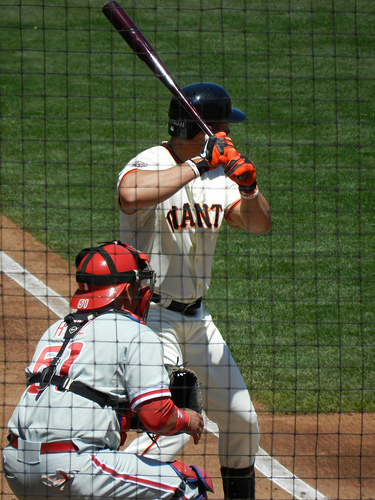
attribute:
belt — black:
[155, 290, 207, 313]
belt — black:
[154, 291, 218, 321]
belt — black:
[153, 295, 207, 318]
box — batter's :
[28, 364, 312, 498]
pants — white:
[124, 296, 260, 484]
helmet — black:
[160, 78, 247, 135]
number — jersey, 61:
[19, 340, 82, 393]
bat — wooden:
[107, 37, 229, 180]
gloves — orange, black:
[185, 143, 255, 189]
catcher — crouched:
[18, 214, 165, 494]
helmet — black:
[129, 59, 287, 132]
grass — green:
[282, 268, 372, 351]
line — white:
[54, 290, 341, 476]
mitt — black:
[177, 351, 202, 425]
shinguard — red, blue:
[155, 459, 221, 482]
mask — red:
[69, 264, 154, 320]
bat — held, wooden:
[64, 16, 246, 166]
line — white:
[242, 446, 312, 484]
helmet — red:
[77, 237, 147, 309]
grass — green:
[256, 286, 372, 359]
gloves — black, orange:
[193, 118, 261, 182]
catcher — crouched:
[37, 239, 203, 481]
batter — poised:
[107, 103, 331, 383]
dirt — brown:
[8, 420, 353, 493]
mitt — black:
[182, 370, 205, 418]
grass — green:
[269, 64, 370, 340]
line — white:
[12, 253, 50, 326]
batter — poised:
[111, 92, 267, 349]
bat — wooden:
[108, 34, 252, 152]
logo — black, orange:
[158, 208, 242, 246]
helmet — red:
[71, 244, 176, 331]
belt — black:
[161, 293, 211, 317]